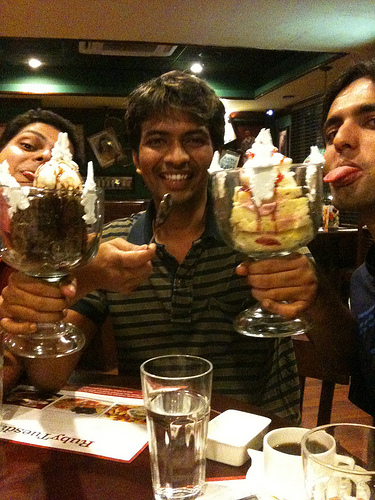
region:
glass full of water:
[121, 341, 239, 498]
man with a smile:
[126, 94, 221, 199]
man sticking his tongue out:
[307, 94, 373, 215]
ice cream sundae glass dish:
[208, 128, 350, 344]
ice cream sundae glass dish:
[2, 123, 105, 363]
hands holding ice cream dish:
[0, 160, 102, 345]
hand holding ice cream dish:
[223, 174, 329, 348]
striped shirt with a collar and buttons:
[110, 213, 247, 366]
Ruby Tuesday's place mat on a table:
[2, 383, 137, 467]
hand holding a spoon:
[102, 180, 190, 303]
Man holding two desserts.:
[7, 63, 326, 393]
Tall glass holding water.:
[102, 324, 246, 494]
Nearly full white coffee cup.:
[259, 407, 346, 494]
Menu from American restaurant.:
[0, 386, 210, 464]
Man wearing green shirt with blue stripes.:
[61, 79, 311, 413]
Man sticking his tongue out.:
[270, 43, 373, 363]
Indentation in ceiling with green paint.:
[0, 25, 342, 119]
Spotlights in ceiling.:
[18, 50, 217, 82]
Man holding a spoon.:
[10, 105, 198, 282]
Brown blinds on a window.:
[269, 89, 374, 225]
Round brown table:
[1, 365, 373, 498]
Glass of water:
[140, 355, 212, 499]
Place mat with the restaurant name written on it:
[0, 381, 156, 463]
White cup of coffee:
[263, 425, 355, 498]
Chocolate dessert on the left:
[0, 132, 134, 357]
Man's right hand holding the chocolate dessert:
[0, 271, 77, 332]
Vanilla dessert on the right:
[214, 125, 322, 336]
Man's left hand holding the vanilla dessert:
[234, 252, 322, 316]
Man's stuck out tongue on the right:
[323, 163, 358, 181]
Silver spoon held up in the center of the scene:
[147, 192, 176, 243]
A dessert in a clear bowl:
[198, 122, 326, 269]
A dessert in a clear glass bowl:
[5, 167, 102, 305]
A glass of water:
[132, 350, 217, 497]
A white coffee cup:
[256, 423, 299, 498]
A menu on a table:
[24, 376, 93, 463]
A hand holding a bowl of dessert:
[220, 220, 322, 352]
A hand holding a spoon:
[103, 192, 190, 311]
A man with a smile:
[106, 64, 256, 247]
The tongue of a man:
[307, 147, 362, 207]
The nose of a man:
[152, 143, 194, 170]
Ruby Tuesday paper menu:
[11, 407, 124, 469]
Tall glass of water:
[123, 348, 234, 498]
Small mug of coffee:
[256, 416, 348, 499]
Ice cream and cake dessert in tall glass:
[201, 117, 339, 342]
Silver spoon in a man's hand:
[129, 189, 187, 269]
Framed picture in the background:
[87, 112, 128, 175]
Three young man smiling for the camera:
[13, 81, 373, 201]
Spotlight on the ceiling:
[11, 44, 65, 105]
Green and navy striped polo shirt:
[91, 206, 314, 423]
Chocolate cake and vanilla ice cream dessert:
[9, 148, 110, 314]